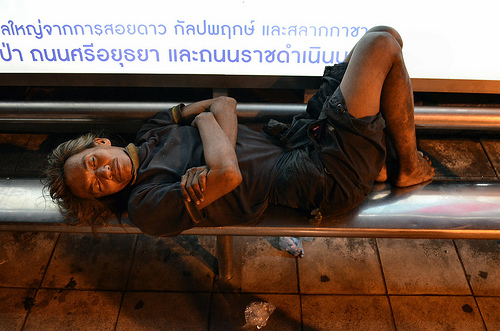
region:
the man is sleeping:
[41, 112, 257, 227]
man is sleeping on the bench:
[53, 94, 416, 226]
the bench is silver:
[14, 175, 51, 232]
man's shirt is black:
[123, 119, 284, 225]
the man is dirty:
[44, 57, 452, 242]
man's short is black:
[290, 83, 387, 201]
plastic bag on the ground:
[220, 290, 287, 327]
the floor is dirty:
[284, 258, 435, 308]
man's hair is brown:
[38, 125, 105, 220]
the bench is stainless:
[396, 195, 495, 250]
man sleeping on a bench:
[46, 23, 443, 233]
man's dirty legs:
[343, 27, 420, 174]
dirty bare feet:
[378, 155, 437, 192]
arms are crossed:
[178, 92, 244, 206]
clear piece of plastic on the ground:
[238, 295, 278, 330]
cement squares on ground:
[0, 226, 499, 329]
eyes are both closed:
[86, 151, 109, 198]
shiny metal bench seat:
[1, 169, 499, 253]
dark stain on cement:
[17, 272, 56, 313]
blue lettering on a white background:
[1, 15, 368, 75]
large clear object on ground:
[231, 297, 280, 329]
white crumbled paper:
[278, 235, 315, 253]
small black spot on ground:
[313, 271, 340, 288]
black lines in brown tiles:
[96, 266, 163, 321]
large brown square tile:
[298, 238, 402, 316]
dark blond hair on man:
[41, 143, 81, 211]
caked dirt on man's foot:
[391, 87, 437, 181]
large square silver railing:
[17, 88, 139, 134]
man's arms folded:
[168, 94, 251, 219]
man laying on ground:
[56, 41, 428, 217]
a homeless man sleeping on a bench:
[40, 80, 450, 214]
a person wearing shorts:
[278, 52, 384, 222]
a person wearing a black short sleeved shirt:
[125, 111, 213, 226]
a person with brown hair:
[44, 135, 101, 216]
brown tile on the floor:
[381, 247, 490, 327]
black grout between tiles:
[373, 265, 397, 307]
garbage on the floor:
[261, 231, 325, 327]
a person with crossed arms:
[175, 97, 240, 207]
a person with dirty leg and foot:
[383, 67, 440, 192]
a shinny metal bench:
[443, 179, 497, 244]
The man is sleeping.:
[25, 129, 157, 214]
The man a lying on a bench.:
[61, 93, 497, 232]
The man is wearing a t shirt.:
[130, 95, 330, 218]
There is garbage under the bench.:
[226, 271, 281, 324]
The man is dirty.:
[342, 73, 439, 173]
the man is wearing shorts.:
[260, 87, 380, 284]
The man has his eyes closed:
[58, 128, 116, 203]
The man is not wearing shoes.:
[360, 115, 450, 191]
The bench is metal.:
[372, 165, 497, 248]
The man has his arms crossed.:
[165, 98, 252, 205]